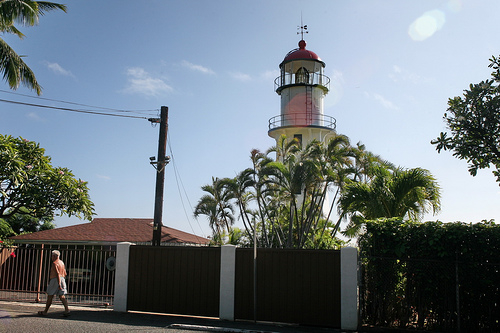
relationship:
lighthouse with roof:
[267, 41, 358, 247] [276, 39, 326, 61]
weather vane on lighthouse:
[290, 11, 310, 41] [267, 41, 358, 247]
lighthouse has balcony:
[267, 41, 358, 247] [271, 74, 332, 91]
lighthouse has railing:
[267, 41, 358, 247] [265, 112, 339, 130]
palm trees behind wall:
[193, 133, 422, 243] [118, 239, 360, 329]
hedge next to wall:
[360, 214, 500, 327] [118, 239, 360, 329]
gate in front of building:
[2, 240, 115, 308] [7, 217, 214, 308]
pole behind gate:
[151, 103, 172, 243] [2, 240, 115, 308]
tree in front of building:
[2, 134, 97, 240] [7, 217, 214, 308]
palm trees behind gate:
[193, 133, 422, 243] [2, 240, 115, 308]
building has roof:
[7, 217, 214, 308] [11, 216, 221, 245]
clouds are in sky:
[116, 58, 213, 97] [1, 1, 497, 142]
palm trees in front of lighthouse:
[193, 133, 422, 243] [267, 41, 358, 247]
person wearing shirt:
[34, 248, 73, 318] [50, 259, 68, 279]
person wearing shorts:
[34, 248, 73, 318] [46, 276, 68, 299]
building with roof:
[12, 217, 211, 308] [11, 216, 221, 245]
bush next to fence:
[360, 214, 500, 327] [122, 242, 499, 332]